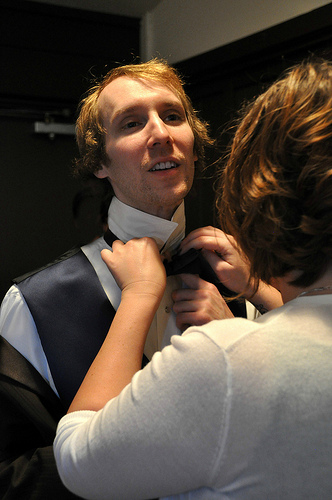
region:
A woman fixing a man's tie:
[90, 74, 329, 498]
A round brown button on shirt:
[165, 304, 177, 322]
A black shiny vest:
[14, 241, 210, 453]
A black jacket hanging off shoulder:
[1, 333, 97, 499]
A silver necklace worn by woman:
[288, 284, 330, 305]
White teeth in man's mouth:
[147, 154, 183, 178]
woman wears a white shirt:
[45, 248, 324, 484]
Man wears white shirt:
[12, 191, 280, 458]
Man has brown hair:
[60, 50, 211, 201]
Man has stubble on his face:
[100, 136, 210, 209]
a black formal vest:
[23, 234, 275, 446]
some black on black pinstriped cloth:
[2, 334, 66, 491]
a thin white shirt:
[62, 292, 330, 498]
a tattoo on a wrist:
[212, 259, 281, 323]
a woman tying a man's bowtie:
[57, 46, 327, 348]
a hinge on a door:
[1, 93, 91, 153]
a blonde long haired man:
[65, 47, 218, 234]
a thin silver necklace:
[289, 281, 331, 301]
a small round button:
[163, 300, 174, 316]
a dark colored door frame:
[144, 6, 326, 83]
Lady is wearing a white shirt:
[220, 347, 328, 451]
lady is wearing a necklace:
[301, 282, 330, 297]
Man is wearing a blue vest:
[43, 278, 84, 322]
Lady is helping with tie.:
[169, 249, 206, 274]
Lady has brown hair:
[258, 114, 322, 183]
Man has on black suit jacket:
[14, 395, 50, 430]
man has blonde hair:
[129, 66, 181, 79]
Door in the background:
[24, 133, 59, 183]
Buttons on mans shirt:
[162, 303, 170, 313]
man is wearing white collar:
[113, 209, 150, 229]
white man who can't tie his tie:
[0, 57, 259, 499]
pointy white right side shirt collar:
[107, 196, 178, 252]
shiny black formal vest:
[12, 244, 247, 411]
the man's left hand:
[163, 250, 235, 330]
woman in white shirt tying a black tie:
[52, 51, 331, 499]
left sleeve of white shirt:
[53, 293, 331, 499]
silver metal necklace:
[297, 285, 331, 294]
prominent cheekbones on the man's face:
[94, 72, 197, 205]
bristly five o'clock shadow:
[105, 132, 195, 218]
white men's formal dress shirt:
[0, 196, 261, 397]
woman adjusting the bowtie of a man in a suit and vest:
[4, 51, 323, 495]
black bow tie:
[100, 227, 227, 275]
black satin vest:
[7, 245, 169, 420]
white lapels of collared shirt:
[109, 193, 191, 259]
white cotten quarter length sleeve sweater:
[51, 286, 329, 498]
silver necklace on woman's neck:
[290, 282, 330, 299]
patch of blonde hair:
[106, 61, 193, 91]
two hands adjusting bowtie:
[100, 224, 254, 295]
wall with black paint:
[7, 26, 67, 248]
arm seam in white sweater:
[208, 377, 238, 483]